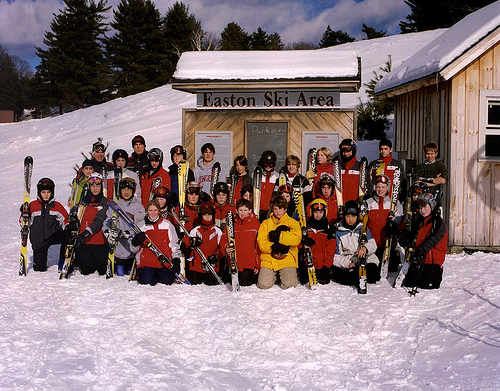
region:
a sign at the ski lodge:
[189, 73, 366, 120]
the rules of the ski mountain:
[206, 129, 233, 161]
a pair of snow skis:
[20, 152, 35, 271]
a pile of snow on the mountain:
[41, 285, 198, 361]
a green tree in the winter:
[32, 13, 120, 110]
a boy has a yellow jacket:
[251, 210, 302, 277]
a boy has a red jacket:
[225, 206, 260, 268]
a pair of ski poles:
[177, 220, 218, 282]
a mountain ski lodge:
[439, 78, 495, 198]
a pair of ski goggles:
[372, 173, 389, 188]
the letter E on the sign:
[202, 89, 216, 108]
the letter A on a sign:
[210, 96, 225, 110]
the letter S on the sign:
[220, 94, 233, 109]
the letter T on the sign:
[228, 90, 237, 111]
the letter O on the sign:
[236, 95, 249, 113]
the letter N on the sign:
[245, 94, 256, 109]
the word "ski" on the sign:
[263, 88, 292, 109]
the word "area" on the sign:
[294, 89, 342, 108]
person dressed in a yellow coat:
[255, 196, 300, 287]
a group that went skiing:
[22, 131, 458, 293]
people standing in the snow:
[13, 133, 456, 279]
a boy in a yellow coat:
[255, 200, 300, 276]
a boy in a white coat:
[335, 205, 375, 270]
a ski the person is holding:
[220, 207, 245, 292]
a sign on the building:
[195, 92, 330, 107]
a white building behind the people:
[175, 51, 356, 156]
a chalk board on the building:
[245, 116, 291, 157]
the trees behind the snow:
[15, 0, 195, 80]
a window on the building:
[480, 96, 495, 158]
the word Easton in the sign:
[200, 89, 257, 109]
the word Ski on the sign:
[264, 89, 293, 107]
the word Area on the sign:
[296, 89, 332, 108]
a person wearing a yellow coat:
[255, 194, 301, 288]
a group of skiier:
[19, 124, 459, 290]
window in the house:
[480, 90, 499, 162]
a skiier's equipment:
[17, 152, 34, 273]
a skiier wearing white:
[327, 200, 379, 288]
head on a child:
[422, 143, 441, 163]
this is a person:
[13, 167, 81, 309]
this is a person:
[70, 172, 122, 289]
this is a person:
[134, 193, 191, 276]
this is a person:
[186, 202, 237, 281]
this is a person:
[257, 194, 308, 304]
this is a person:
[329, 185, 373, 288]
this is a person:
[67, 134, 119, 219]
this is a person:
[106, 114, 164, 201]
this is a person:
[160, 127, 195, 208]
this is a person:
[172, 134, 240, 234]